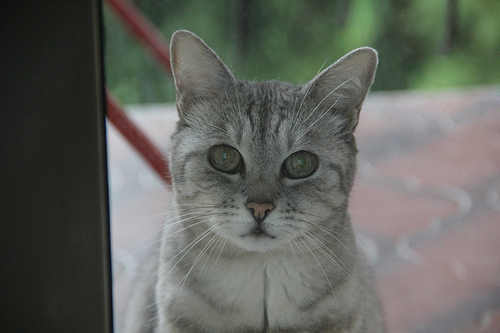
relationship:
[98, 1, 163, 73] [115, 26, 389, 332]
rail behind cat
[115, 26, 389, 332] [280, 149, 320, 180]
cat has eyes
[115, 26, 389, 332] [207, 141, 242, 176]
cat has right eye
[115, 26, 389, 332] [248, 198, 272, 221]
cat has nose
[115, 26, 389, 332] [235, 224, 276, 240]
cat has mouth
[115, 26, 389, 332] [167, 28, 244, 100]
cat has ears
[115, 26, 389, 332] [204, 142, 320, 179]
cat has eyes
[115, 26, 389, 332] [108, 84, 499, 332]
cat on top of floor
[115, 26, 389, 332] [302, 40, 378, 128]
cat has left ear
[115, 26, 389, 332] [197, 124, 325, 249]
cat has face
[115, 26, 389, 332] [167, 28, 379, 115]
cat has ears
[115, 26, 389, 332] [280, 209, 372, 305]
cat has whiskers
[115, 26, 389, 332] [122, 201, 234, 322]
cat has whiskers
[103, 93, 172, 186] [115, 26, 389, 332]
rail behind cat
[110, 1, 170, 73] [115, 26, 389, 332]
rail behind cat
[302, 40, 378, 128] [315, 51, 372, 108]
left ear has inside